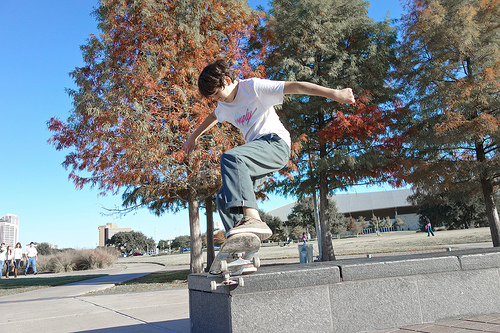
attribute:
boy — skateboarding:
[186, 59, 356, 240]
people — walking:
[0, 239, 38, 279]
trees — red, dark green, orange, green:
[43, 2, 500, 262]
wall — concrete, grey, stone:
[185, 246, 499, 333]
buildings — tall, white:
[0, 215, 20, 248]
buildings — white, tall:
[98, 221, 114, 249]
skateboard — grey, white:
[207, 232, 261, 292]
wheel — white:
[254, 258, 261, 269]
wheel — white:
[218, 261, 228, 275]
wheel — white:
[209, 281, 217, 292]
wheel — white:
[236, 276, 245, 290]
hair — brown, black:
[196, 63, 235, 96]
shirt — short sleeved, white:
[209, 78, 291, 145]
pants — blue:
[217, 134, 293, 239]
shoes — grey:
[226, 221, 271, 239]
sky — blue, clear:
[1, 3, 499, 250]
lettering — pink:
[233, 109, 256, 125]